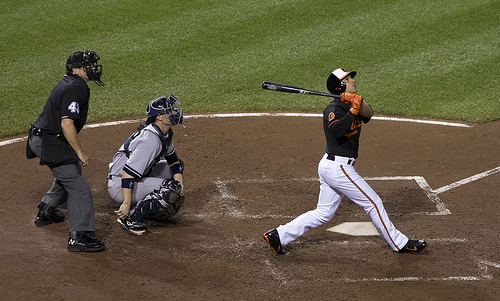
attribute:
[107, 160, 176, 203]
pants — grey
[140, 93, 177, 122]
helmet — black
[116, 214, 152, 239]
shoes — in the picture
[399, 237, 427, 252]
shoe — black, orange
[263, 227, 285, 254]
shoe — orange, black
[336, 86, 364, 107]
player — in the picture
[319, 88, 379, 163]
shirt — black, orange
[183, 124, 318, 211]
dirt — brown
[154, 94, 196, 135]
helmet — black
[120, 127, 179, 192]
shirt — black, grey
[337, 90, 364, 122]
gloves — black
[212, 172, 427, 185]
line — white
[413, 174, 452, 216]
line — white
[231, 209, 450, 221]
line — white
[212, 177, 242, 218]
line — white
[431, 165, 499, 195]
line — white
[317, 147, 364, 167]
belt — black